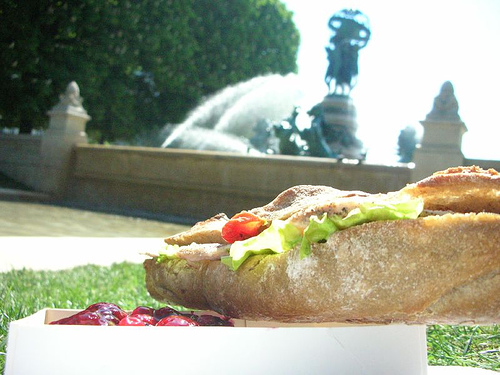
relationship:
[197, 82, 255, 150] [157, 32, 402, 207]
water spraying in fountain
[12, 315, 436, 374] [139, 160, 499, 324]
box under sandwich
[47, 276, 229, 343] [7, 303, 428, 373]
sauce in box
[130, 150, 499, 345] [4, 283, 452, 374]
sandwich balanced on box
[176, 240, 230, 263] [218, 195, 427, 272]
meat next to lettuce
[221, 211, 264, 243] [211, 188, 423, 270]
tomato on top of lettuce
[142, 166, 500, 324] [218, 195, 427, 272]
bread on lettuce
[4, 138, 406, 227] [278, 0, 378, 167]
beige wall around fountain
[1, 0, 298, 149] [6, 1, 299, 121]
tree with leaves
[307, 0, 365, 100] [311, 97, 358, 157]
statue on pillar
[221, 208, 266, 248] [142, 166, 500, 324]
tomato on bread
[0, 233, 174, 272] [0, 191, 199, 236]
path next to grass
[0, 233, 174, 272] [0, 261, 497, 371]
path next to grass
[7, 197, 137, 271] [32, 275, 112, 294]
white reflection next to grass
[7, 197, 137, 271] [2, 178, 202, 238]
white reflection next to floor